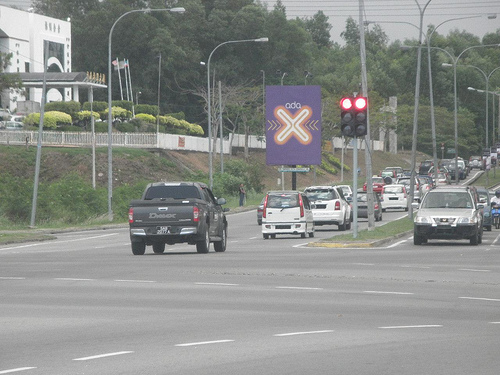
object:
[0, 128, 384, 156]
fence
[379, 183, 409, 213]
vehicle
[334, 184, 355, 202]
vehicle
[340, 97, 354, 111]
street light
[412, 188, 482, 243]
car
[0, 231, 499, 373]
intersection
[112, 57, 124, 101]
flags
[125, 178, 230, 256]
truck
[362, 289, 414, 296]
lines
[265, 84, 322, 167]
sign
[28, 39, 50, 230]
pole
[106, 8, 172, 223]
pole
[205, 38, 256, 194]
pole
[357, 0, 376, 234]
pole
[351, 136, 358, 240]
pole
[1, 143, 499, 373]
ground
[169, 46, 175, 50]
leaves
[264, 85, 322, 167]
billboard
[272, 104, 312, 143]
"x"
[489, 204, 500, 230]
motorcycle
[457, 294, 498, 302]
line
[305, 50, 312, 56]
leaves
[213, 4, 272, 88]
tree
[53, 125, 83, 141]
bush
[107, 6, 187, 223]
street light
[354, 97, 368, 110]
signal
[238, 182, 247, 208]
person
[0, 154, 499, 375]
road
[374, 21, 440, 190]
light post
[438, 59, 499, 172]
light post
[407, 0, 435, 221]
light post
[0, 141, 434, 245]
grass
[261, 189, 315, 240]
vehicle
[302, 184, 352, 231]
vehicle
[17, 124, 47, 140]
bush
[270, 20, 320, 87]
trees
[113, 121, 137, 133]
bushes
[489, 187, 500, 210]
person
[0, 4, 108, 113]
building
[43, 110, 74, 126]
hydrangeas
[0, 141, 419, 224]
hill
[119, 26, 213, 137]
tree